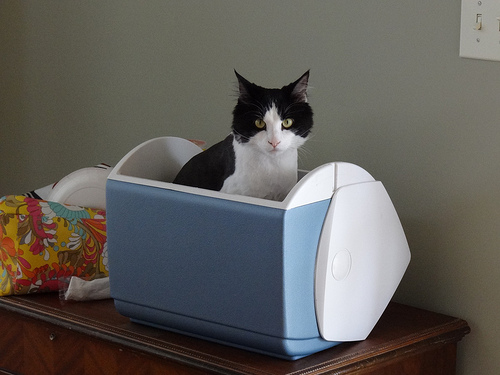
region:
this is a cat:
[182, 72, 322, 170]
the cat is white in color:
[241, 157, 286, 192]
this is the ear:
[288, 65, 321, 97]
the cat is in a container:
[132, 186, 338, 320]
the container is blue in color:
[186, 235, 271, 304]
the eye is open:
[279, 118, 293, 128]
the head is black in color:
[258, 82, 291, 100]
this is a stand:
[384, 314, 451, 369]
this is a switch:
[471, 14, 482, 34]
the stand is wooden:
[394, 312, 441, 372]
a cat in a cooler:
[102, 62, 410, 358]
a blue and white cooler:
[105, 136, 412, 361]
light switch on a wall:
[459, 0, 499, 59]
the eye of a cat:
[254, 118, 266, 129]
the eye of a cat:
[281, 118, 293, 128]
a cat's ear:
[232, 68, 254, 95]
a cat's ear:
[283, 68, 309, 105]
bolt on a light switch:
[476, 37, 481, 44]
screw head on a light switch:
[476, 0, 481, 7]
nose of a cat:
[267, 137, 281, 148]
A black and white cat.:
[198, 52, 308, 187]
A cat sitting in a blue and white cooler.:
[135, 70, 358, 345]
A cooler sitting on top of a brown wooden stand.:
[88, 181, 404, 371]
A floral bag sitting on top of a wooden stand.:
[5, 212, 101, 320]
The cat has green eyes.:
[250, 110, 265, 135]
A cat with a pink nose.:
[266, 136, 277, 146]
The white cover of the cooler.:
[316, 176, 416, 341]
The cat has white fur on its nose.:
[266, 118, 281, 141]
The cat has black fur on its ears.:
[243, 72, 304, 97]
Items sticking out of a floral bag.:
[32, 167, 107, 214]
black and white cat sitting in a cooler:
[106, 68, 413, 363]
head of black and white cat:
[232, 70, 316, 156]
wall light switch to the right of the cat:
[459, 0, 499, 60]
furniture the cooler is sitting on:
[2, 299, 470, 373]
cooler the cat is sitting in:
[106, 140, 412, 360]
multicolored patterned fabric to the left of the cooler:
[1, 195, 104, 293]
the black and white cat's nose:
[267, 137, 282, 147]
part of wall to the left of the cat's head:
[2, 0, 229, 133]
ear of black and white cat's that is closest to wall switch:
[287, 68, 314, 102]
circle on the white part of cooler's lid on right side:
[331, 245, 355, 282]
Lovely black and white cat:
[215, 63, 331, 158]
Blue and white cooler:
[101, 151, 382, 358]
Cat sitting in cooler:
[103, 58, 447, 353]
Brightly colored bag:
[2, 199, 89, 294]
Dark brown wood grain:
[27, 325, 194, 370]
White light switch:
[452, 12, 497, 74]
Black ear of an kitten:
[223, 58, 262, 102]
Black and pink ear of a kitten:
[278, 71, 320, 108]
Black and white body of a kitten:
[180, 143, 287, 208]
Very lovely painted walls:
[39, 33, 156, 120]